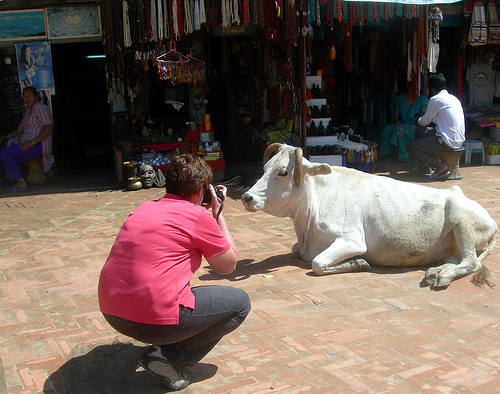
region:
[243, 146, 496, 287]
a type of cattle laying on the ground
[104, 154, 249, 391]
a photographer in a red shirt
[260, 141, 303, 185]
two horns turned inward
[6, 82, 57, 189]
a woman sitting down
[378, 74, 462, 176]
a man and a woman sitting down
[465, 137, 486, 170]
foot stools stacked on each other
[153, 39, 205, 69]
two pink hangers next to each other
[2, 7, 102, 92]
artwork above the woman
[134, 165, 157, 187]
a mask on the ground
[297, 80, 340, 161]
statues on a shelf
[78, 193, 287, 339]
a woman with a pink shirt on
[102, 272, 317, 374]
a woman with pants on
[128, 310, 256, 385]
a woman wearing shoes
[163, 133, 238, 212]
the head of a woman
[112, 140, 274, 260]
a woman taking a picture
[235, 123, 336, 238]
the head of a cow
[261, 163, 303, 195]
the eye of a cow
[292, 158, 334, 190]
the ear of a cow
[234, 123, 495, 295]
a cow lying on the ground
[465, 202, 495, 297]
the tail of a cow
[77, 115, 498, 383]
The man is taking a picture of a cow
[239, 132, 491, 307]
The cow is sitting on the ground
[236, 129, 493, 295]
The white cow has horns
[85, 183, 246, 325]
The man is wearing a red shirt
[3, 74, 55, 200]
A lady is sitting on a stool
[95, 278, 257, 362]
The man is wearing black jeans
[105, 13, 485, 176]
The business is selling items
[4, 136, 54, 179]
The woman is wearing purple pants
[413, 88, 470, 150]
The man is wearing a white shirt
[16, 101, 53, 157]
The woman is wearing a striped shirt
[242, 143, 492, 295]
a white cow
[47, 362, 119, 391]
a shadow on the ground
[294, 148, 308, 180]
horns on the cow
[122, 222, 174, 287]
women wearing a pink shirt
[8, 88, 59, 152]
a person sitting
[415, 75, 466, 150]
a man sitting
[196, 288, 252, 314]
the person is wearing jeans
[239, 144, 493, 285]
the cow is laying down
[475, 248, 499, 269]
the cows tail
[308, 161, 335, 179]
the ear of the cow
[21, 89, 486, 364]
a man on a sidewalk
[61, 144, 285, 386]
a man kneeling on a sidewalk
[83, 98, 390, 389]
a man taking a picture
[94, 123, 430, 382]
a man taking a picture of an animal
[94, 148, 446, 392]
a man taking a picture outside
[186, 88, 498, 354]
a cow laying down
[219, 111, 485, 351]
a cow laying on the sidewalk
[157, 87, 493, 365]
cow on a sidewalk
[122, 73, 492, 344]
man looking at cow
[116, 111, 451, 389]
man taking picture of white cows